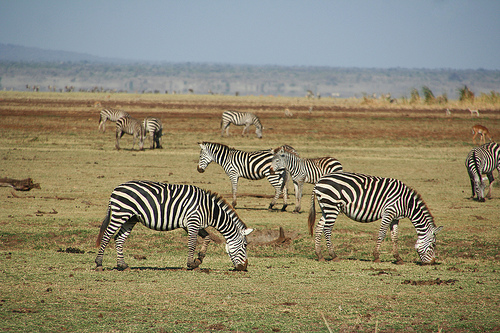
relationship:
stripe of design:
[314, 186, 341, 201] [315, 172, 380, 208]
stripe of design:
[319, 197, 343, 206] [315, 172, 380, 208]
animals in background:
[444, 103, 483, 118] [0, 50, 499, 155]